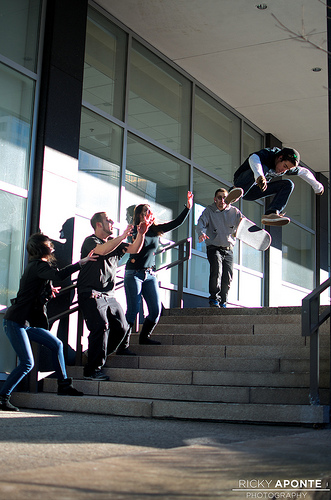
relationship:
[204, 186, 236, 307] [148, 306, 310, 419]
man standing on staircase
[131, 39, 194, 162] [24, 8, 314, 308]
window inside of building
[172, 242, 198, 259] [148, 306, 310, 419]
rail next to staircase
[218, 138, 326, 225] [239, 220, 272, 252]
man jumping on skateboard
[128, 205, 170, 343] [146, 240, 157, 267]
woman wearing sweater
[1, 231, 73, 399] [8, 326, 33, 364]
woman wearing jeans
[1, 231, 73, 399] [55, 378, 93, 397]
woman wearing boots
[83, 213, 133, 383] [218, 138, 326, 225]
man watching man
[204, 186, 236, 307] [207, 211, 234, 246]
man wearing sweatshirt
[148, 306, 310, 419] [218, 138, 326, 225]
staircase under man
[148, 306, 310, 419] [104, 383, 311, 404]
staircase has step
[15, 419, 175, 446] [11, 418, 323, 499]
shadow cast on sidewalk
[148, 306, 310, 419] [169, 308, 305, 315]
staircase has step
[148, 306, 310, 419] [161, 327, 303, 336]
staircase has step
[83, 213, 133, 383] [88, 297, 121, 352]
man wearing jeans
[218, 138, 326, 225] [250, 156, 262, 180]
man has sleeve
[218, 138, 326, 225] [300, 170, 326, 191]
man has sleeve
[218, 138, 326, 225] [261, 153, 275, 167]
man wearing t-shirt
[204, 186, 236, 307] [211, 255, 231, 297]
man wearing pants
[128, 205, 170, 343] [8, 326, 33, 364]
woman wearing jeans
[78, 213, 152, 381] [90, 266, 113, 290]
man wearing shirt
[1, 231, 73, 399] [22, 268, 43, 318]
woman wearing sweatshirt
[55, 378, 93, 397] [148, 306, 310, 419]
boots on top of staircase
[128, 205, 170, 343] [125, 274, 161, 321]
woman wearing jeans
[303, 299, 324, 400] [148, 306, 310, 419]
rail attached to staircase